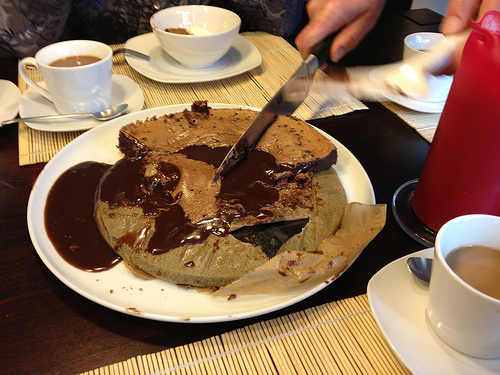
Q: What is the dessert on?
A: Plate.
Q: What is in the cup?
A: Coffee.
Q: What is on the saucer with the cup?
A: Spoon.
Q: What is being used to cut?
A: Knife.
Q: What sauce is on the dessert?
A: Chocolate.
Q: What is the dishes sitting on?
A: Table.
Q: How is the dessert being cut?
A: A knife.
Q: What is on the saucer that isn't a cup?
A: Bowl.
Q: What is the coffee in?
A: Cups.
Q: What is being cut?
A: Desert.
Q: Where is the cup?
A: On plate.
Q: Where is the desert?
A: On the plate.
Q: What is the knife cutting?
A: Desert.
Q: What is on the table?
A: Placemat.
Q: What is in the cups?
A: Brown beverage.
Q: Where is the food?
A: Plate.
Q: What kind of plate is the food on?
A: White round plate.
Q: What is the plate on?
A: Table.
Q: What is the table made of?
A: Wood.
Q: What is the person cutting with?
A: Knife.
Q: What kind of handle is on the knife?
A: Black plastic handle.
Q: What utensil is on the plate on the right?
A: Spoon.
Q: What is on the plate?
A: A cake.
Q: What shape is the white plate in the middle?
A: Round.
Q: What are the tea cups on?
A: White saucers.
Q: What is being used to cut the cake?
A: A knife.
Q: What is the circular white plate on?
A: A dark wood table.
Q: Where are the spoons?
A: Next to the tea cups.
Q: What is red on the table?
A: A candle.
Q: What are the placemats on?
A: A wooden table.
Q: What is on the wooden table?
A: A white plate.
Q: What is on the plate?
A: Dessert.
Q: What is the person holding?
A: A knife.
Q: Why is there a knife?
A: To cut the dessert.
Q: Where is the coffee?
A: In the mugs.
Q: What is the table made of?
A: Wood.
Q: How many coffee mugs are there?
A: Four.